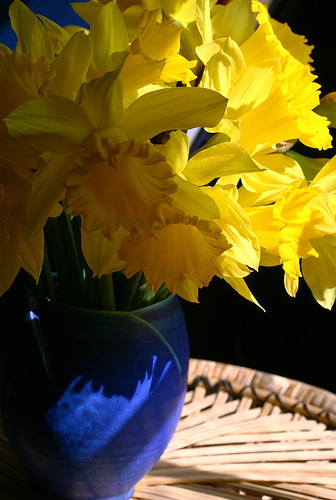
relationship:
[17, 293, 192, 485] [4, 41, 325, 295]
vase of flowers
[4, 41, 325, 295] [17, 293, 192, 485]
flowers in vase